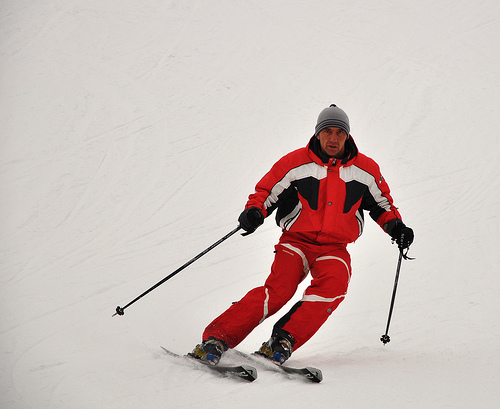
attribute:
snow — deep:
[33, 70, 260, 174]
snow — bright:
[51, 42, 230, 194]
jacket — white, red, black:
[295, 145, 375, 240]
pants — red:
[202, 230, 350, 368]